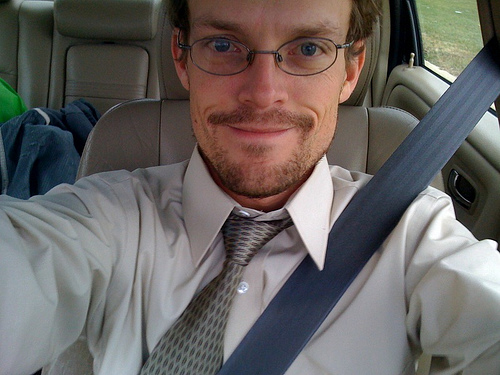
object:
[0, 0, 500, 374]
man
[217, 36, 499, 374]
seatbelt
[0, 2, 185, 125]
beige seats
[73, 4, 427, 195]
beige seats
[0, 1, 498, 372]
car